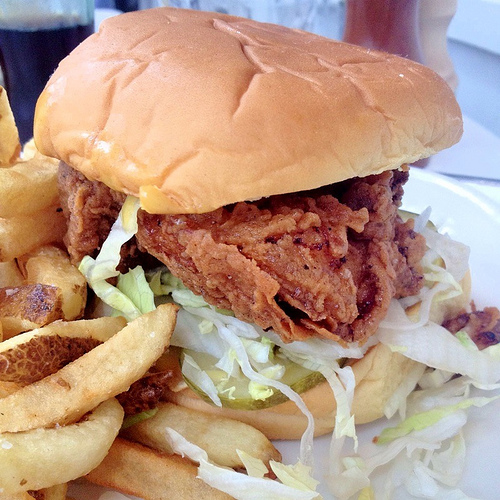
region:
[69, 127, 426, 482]
the burger has chicken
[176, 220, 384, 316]
crispy crunchy bacon slices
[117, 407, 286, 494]
two golden french fries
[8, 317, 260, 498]
pile of homemade french fries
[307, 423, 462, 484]
pieces of shredded lettuce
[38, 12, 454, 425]
chicken sandwich with bacon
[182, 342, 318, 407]
crisp green dill pickle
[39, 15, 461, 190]
top of a bun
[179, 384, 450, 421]
bottom part of a bun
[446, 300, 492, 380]
fallen piece of bacon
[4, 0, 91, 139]
glass of soda pop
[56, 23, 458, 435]
this is a burger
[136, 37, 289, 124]
this is some bread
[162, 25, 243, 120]
the bread is brown in color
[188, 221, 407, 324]
this is some meat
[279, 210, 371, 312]
the meat is brown in color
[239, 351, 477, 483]
this is some coleslaw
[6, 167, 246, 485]
these are some French fries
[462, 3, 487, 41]
this is the wall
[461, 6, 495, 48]
the wall is white in color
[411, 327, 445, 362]
the piece is white in color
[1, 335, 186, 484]
french fries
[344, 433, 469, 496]
lettuce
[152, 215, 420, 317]
fried chicken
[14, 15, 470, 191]
half of a sandwich bun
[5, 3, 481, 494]
A fried chicken sandwich with lettuce and pickles and a side of fries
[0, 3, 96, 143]
a drink in a glass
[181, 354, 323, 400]
pickle slice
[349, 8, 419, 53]
ketchup bottle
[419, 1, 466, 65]
mustard bottle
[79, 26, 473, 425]
fired chicken between 2 pieces of bread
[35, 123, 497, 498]
a small white plate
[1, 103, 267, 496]
crispy golden french fries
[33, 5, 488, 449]
a chicken sandwich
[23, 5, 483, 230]
the top bun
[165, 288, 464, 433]
the bottom bun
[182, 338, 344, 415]
a slice of dill pickle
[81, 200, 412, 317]
a crunchy fried chicken breast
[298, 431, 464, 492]
shredded iceberg lettuce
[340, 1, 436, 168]
a bottle of ketchup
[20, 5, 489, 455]
a fried chicken sandwich on a bun